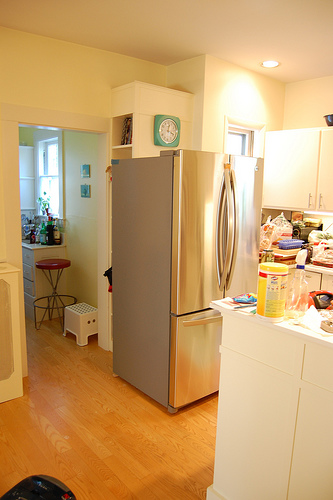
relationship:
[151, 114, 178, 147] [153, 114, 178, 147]
border on clock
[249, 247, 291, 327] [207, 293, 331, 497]
container on top of counter top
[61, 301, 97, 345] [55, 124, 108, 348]
foot stool near wall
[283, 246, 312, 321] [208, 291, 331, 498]
bottle on top of counter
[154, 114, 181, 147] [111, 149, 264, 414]
clock hanging above fridge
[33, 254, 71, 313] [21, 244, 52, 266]
stool near counter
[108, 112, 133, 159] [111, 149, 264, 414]
shelf standing behind fridge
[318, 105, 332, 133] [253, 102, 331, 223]
bowl sitting on top of cabinets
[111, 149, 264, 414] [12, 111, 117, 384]
fridge standing near doorway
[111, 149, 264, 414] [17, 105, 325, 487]
fridge in kitchen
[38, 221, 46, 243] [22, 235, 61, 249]
bottle on counter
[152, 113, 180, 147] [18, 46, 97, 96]
clock on wall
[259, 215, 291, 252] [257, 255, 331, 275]
bag on counter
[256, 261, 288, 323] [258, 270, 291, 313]
container has disinfecting wipes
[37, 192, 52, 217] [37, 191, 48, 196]
green plant has leaves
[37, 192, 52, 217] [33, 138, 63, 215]
green plant in front of window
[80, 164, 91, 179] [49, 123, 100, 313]
painting hanging on wall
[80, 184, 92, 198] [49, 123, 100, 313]
painting hanging on wall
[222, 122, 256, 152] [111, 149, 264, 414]
window on side of fridge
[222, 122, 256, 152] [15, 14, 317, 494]
window in kitchen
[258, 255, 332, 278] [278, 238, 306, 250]
counter with item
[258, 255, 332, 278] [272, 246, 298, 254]
counter with item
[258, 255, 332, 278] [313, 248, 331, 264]
counter with item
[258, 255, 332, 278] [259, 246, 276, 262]
counter with item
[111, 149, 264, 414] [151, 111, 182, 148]
fridge under clock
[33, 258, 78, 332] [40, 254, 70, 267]
stool with a seat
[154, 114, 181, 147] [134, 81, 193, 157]
clock on wall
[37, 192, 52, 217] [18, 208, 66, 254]
green plant on windowsill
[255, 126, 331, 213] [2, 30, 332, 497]
cabinets in kitchen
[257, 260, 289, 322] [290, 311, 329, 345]
wipes sitting on top of counter